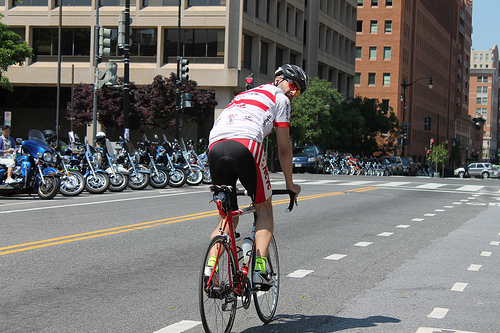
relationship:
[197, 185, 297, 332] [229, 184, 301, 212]
bicycle has handle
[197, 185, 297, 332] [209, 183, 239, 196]
bicycle has seat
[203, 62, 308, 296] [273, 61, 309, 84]
man wearing helmet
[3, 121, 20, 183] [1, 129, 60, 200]
man on motorcycle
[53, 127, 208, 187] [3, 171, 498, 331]
motorcycles on road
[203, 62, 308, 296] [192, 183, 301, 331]
man riding bicycle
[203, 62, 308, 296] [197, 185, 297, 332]
man riding bicycle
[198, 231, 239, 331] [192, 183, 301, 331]
wheel of bicycle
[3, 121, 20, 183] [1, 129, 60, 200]
person on motorcycle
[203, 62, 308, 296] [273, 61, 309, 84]
man with helmet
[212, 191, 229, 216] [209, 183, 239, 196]
pack on seat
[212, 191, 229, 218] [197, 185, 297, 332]
bottle on bicycle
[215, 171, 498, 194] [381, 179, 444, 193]
crosswalk has stripes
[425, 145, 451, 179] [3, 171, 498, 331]
tree on street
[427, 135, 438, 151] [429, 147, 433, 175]
stoplight on post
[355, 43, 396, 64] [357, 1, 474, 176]
windows on building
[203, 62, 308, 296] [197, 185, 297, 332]
man on bicycle